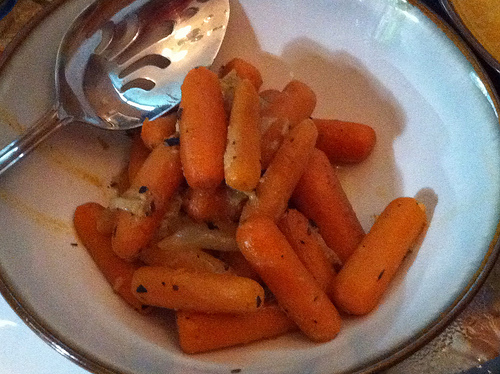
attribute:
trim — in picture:
[428, 26, 483, 108]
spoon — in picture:
[51, 10, 184, 134]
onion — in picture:
[107, 187, 154, 217]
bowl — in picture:
[9, 9, 482, 371]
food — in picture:
[86, 79, 427, 349]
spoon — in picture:
[53, 0, 254, 127]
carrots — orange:
[73, 200, 155, 311]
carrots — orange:
[131, 261, 266, 311]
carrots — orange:
[173, 295, 294, 352]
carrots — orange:
[234, 211, 345, 343]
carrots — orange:
[330, 194, 427, 322]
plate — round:
[27, 51, 482, 344]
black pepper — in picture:
[131, 279, 153, 296]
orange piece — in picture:
[238, 221, 339, 332]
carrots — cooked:
[134, 102, 369, 332]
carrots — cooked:
[71, 56, 426, 354]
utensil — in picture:
[436, 20, 497, 75]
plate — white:
[361, 8, 498, 116]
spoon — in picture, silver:
[0, 1, 233, 178]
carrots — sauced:
[93, 89, 399, 286]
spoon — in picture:
[3, 1, 257, 256]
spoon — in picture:
[5, 5, 227, 166]